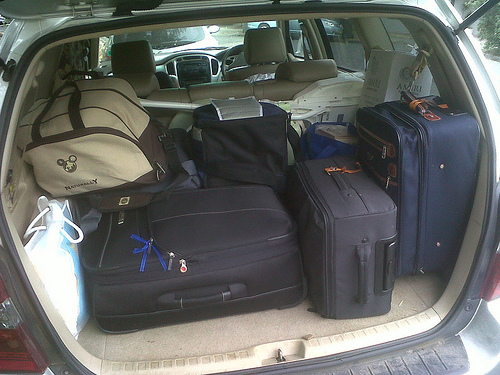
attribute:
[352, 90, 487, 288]
suitcase — traveling, blue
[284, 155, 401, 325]
suitcase — traveling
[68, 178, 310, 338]
suitcase — traveling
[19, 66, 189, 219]
suitcase — traveling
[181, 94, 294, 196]
suitcase — traveling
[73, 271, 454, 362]
floor — beige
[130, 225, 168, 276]
ribbon — blue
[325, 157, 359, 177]
ribbon — orange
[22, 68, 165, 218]
bag — brown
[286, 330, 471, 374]
rubber — black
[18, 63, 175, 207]
backpack — brown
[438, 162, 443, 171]
rivet — silver, metal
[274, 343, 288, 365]
rear/door latch — on vehicle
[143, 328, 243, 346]
carpet — on floor, in vehicle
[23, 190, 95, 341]
white bag — sitting in car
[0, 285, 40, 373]
red/tail light — on vehicle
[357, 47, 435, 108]
white/cardboard box — in car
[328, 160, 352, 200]
black handle — on suitcase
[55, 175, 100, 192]
text — on brown backpack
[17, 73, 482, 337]
luggage — in back of vehicle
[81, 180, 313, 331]
luggage piece — in van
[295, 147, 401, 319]
luggage piece — in van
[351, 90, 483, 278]
luggage piece — in van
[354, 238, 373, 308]
handle — on a suitcase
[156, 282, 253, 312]
handle — on a suitcase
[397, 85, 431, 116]
handle — on a suitcase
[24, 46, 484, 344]
cargo area — a mini vans, packed with traveling suit cases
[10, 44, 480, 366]
cargo area — packed with traveling suit cases, a mini vans